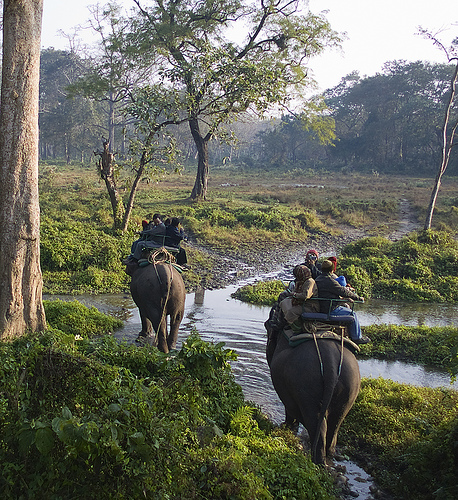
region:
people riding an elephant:
[279, 243, 366, 469]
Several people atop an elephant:
[262, 258, 367, 349]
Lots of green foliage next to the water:
[42, 359, 267, 482]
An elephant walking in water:
[124, 258, 214, 369]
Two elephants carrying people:
[117, 209, 357, 456]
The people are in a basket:
[284, 258, 363, 334]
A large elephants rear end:
[266, 317, 349, 470]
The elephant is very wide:
[279, 333, 352, 461]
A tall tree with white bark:
[12, 149, 52, 342]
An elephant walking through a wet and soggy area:
[256, 113, 396, 364]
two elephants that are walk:
[75, 162, 381, 498]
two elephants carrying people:
[79, 140, 419, 486]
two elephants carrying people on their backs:
[88, 149, 433, 479]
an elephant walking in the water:
[207, 190, 426, 498]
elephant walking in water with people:
[57, 111, 425, 491]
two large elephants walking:
[83, 132, 457, 495]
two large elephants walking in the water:
[117, 181, 436, 485]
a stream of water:
[66, 164, 456, 482]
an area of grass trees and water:
[56, 146, 437, 498]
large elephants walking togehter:
[52, 98, 429, 487]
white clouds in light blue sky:
[53, 3, 74, 33]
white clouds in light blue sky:
[310, 7, 346, 41]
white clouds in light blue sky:
[316, 50, 359, 72]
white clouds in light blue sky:
[210, 8, 246, 43]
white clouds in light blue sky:
[50, 6, 98, 49]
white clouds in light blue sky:
[276, 71, 312, 116]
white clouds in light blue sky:
[365, 13, 418, 57]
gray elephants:
[109, 233, 192, 345]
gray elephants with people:
[262, 244, 366, 435]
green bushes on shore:
[60, 394, 138, 444]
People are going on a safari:
[55, 133, 418, 466]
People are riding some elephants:
[66, 139, 398, 484]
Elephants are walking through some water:
[79, 129, 417, 493]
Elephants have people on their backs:
[80, 151, 413, 496]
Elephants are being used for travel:
[42, 114, 425, 478]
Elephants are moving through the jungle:
[47, 101, 416, 489]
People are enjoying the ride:
[69, 160, 400, 465]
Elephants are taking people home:
[49, 145, 409, 475]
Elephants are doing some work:
[74, 152, 408, 477]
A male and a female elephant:
[59, 160, 419, 479]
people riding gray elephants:
[277, 253, 362, 424]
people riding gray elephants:
[117, 204, 200, 351]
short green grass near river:
[41, 307, 105, 351]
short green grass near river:
[8, 359, 89, 401]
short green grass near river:
[101, 380, 210, 423]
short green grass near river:
[186, 396, 253, 464]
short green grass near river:
[28, 405, 102, 462]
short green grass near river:
[123, 421, 193, 474]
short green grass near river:
[369, 381, 410, 447]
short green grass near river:
[232, 190, 299, 253]